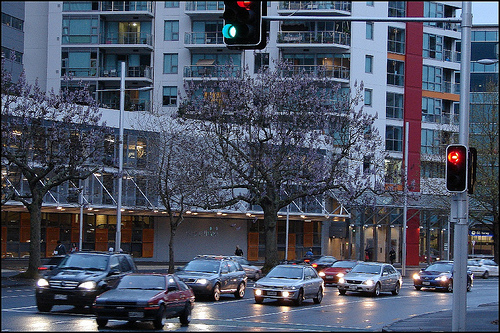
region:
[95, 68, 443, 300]
this is an urban are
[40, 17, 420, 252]
this is a city street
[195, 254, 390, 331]
the cars have lights on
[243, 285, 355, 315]
the headlights are yellow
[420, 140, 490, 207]
the traffic light is red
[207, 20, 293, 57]
the other traffic light is green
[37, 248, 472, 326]
vehicles driving on a road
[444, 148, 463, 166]
bright red traffic light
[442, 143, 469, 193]
black and silver traffic light fixture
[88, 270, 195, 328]
old black and red car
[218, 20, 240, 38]
bright green traffic light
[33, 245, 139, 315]
black SUV with headlights on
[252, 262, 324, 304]
silver car with driving lights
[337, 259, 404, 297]
silver car with headlights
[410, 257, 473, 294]
blue car with headlights on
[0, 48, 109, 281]
tree with purple flowers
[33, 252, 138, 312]
an SUV driving on street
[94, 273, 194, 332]
an car driving on street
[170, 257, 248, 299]
an car driving on street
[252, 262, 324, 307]
an car driving on street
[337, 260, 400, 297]
an car driving on street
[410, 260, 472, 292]
an car driving on street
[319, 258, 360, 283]
an car driving on street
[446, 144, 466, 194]
an electric traffic signal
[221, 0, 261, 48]
an electric traffic signal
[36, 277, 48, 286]
a lit car headlight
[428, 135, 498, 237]
The turn signal is red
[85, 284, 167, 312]
The hood is black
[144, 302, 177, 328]
The left front tire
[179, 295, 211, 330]
The back front tire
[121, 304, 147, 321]
The front license plate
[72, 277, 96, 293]
The right head light on the black SUV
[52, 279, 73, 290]
The emblem of the car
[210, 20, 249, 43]
The light is green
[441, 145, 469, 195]
The traffic light is black in color.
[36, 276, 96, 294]
The car has its front lights on.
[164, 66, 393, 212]
The flowers on the tree are purple.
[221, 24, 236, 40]
The light is shining green.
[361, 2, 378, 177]
The side of the building has many windows.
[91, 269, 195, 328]
The car is red and black.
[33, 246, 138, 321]
The SUV is black in color.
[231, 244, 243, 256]
The person is walking on the sidewalk.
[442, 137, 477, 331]
a tall pole with a light on it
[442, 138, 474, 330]
a traffic light with a red light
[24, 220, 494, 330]
a road packed with cars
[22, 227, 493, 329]
a street lined with automobiles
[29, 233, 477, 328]
cars start to move through the intersection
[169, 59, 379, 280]
this is the largest tree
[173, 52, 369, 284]
the tree is starting to produce buds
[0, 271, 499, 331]
the road surface is wet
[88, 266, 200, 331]
this car has has its lights off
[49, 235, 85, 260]
people in the office window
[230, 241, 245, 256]
a man walks down the sidewalk